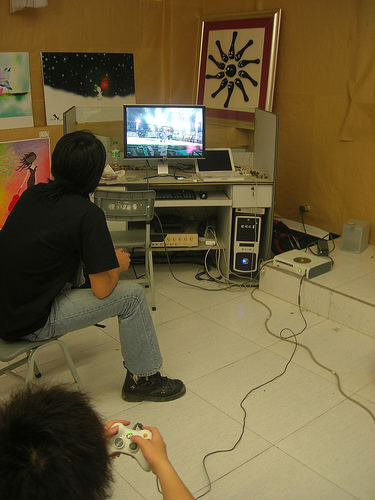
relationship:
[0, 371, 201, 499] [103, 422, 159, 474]
guy holding controller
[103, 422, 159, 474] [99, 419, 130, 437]
controller in h hand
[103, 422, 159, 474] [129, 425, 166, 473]
controller in h hand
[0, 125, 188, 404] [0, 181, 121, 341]
guy wearing a shirt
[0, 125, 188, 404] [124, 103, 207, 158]
guy playing a video game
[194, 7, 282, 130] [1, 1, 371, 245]
artwork hanging on wall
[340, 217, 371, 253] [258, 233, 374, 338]
speaker on step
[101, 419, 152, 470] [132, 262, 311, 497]
controller has cord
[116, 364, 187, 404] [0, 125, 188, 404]
shoe on guy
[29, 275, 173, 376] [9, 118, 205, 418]
jean on man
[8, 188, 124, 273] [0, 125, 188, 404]
shirt on guy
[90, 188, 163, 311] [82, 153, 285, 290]
chair at desk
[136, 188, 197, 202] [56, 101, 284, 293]
keyboard on desk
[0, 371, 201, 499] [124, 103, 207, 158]
guy playing video game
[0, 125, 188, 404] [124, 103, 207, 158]
guy playing video game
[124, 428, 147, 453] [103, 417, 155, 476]
thumb on controller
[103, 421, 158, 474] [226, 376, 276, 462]
controller has cord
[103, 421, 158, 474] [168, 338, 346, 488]
controller laying on ground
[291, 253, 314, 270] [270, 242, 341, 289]
disk on top of console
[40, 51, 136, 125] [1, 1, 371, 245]
artwork leaning on wall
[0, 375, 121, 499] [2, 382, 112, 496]
hair sticking off of head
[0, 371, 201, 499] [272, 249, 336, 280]
guy playing console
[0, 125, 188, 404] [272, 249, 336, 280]
guy playing console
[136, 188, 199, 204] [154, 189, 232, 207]
keyboard on drawer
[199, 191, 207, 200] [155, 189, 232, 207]
mouse on drawer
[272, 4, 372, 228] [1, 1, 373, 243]
paper covering walls